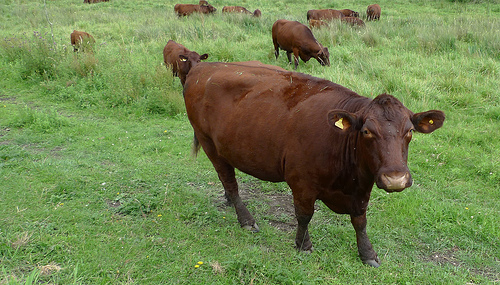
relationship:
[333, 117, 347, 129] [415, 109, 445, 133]
tab in ear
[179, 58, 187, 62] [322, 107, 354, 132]
tab in ear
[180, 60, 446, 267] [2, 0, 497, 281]
cow in field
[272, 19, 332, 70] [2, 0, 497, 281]
cow in field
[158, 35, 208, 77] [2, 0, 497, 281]
cow in field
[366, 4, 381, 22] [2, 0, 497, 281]
cow in field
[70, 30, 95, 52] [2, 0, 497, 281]
cow in field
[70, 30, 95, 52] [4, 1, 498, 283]
cow in grass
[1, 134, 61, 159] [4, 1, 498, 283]
dirt track in grass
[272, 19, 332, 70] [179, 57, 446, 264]
cow grazing in grass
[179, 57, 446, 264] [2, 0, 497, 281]
grass in field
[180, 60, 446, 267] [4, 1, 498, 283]
cow grazing in grass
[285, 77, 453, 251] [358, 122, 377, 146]
cow has eye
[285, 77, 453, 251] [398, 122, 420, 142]
cow has eye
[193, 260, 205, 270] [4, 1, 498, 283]
flower in grass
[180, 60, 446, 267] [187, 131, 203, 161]
cow has tail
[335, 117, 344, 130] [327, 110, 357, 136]
tab in ears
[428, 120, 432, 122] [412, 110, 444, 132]
tags in ears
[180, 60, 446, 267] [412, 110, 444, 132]
cow has ears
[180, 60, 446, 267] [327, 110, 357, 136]
cow has ears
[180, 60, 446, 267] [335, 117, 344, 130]
cow wearing tab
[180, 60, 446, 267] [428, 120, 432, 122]
cow wearing tags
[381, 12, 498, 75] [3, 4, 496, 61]
grass in background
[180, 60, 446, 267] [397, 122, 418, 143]
cow has eye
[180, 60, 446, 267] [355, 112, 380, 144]
cow has eye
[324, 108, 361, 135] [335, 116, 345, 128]
ear has tag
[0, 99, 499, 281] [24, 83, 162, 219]
flowers in grass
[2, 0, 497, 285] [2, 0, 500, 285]
green grass on field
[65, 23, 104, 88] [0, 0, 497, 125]
cow half covered by grass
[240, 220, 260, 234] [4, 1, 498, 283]
hoof in grass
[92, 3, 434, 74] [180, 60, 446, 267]
cows behind cow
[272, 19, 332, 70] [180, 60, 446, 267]
cow behind cow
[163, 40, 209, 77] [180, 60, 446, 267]
cow behind cow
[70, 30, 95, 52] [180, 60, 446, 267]
cow behind cow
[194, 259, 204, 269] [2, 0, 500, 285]
yellow flowers on field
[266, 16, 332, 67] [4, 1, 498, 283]
cow eating grass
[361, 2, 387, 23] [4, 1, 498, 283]
cow eating grass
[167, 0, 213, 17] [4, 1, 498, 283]
cow eating grass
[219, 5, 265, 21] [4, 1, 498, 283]
cow eating grass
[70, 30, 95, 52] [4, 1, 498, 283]
cow eating grass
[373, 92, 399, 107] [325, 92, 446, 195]
tuft on head